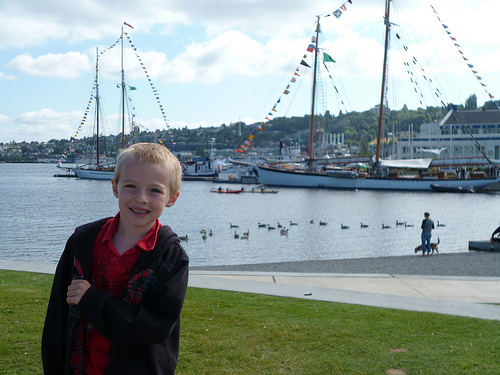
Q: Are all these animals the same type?
A: No, there are both dogs and birds.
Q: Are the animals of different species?
A: Yes, they are dogs and birds.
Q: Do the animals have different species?
A: Yes, they are dogs and birds.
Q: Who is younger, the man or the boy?
A: The boy is younger than the man.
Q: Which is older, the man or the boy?
A: The man is older than the boy.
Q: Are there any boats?
A: Yes, there is a boat.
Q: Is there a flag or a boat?
A: Yes, there is a boat.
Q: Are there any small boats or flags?
A: Yes, there is a small boat.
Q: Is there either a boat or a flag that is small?
A: Yes, the boat is small.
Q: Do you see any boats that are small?
A: Yes, there is a small boat.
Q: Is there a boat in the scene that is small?
A: Yes, there is a boat that is small.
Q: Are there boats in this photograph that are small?
A: Yes, there is a boat that is small.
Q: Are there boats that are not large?
A: Yes, there is a small boat.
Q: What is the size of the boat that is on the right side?
A: The boat is small.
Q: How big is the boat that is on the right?
A: The boat is small.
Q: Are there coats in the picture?
A: Yes, there is a coat.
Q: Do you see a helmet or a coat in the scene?
A: Yes, there is a coat.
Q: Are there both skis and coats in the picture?
A: No, there is a coat but no skis.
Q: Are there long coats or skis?
A: Yes, there is a long coat.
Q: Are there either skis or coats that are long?
A: Yes, the coat is long.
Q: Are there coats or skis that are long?
A: Yes, the coat is long.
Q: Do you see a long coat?
A: Yes, there is a long coat.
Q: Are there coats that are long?
A: Yes, there is a coat that is long.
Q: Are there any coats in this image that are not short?
A: Yes, there is a long coat.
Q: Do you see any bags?
A: No, there are no bags.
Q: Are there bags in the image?
A: No, there are no bags.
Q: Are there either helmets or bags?
A: No, there are no bags or helmets.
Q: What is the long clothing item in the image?
A: The clothing item is a coat.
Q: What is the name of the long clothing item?
A: The clothing item is a coat.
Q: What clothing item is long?
A: The clothing item is a coat.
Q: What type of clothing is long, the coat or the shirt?
A: The coat is long.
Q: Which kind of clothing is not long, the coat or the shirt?
A: The shirt is not long.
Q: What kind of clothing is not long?
A: The clothing is a shirt.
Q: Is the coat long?
A: Yes, the coat is long.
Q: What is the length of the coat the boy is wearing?
A: The coat is long.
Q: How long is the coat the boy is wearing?
A: The coat is long.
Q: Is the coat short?
A: No, the coat is long.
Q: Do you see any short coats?
A: No, there is a coat but it is long.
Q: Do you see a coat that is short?
A: No, there is a coat but it is long.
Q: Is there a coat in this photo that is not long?
A: No, there is a coat but it is long.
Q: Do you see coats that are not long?
A: No, there is a coat but it is long.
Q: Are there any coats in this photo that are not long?
A: No, there is a coat but it is long.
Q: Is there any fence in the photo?
A: No, there are no fences.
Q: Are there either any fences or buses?
A: No, there are no fences or buses.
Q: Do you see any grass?
A: Yes, there is grass.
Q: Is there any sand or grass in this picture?
A: Yes, there is grass.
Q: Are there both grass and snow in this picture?
A: No, there is grass but no snow.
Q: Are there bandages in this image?
A: No, there are no bandages.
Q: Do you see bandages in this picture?
A: No, there are no bandages.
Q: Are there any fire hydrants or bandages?
A: No, there are no bandages or fire hydrants.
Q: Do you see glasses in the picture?
A: No, there are no glasses.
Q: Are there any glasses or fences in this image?
A: No, there are no glasses or fences.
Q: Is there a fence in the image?
A: No, there are no fences.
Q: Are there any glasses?
A: No, there are no glasses.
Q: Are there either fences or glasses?
A: No, there are no glasses or fences.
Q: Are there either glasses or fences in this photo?
A: No, there are no glasses or fences.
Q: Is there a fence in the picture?
A: No, there are no fences.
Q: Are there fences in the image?
A: No, there are no fences.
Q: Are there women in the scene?
A: No, there are no women.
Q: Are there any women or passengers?
A: No, there are no women or passengers.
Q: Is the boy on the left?
A: Yes, the boy is on the left of the image.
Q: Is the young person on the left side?
A: Yes, the boy is on the left of the image.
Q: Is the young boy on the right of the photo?
A: No, the boy is on the left of the image.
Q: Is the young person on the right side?
A: No, the boy is on the left of the image.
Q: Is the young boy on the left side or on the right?
A: The boy is on the left of the image.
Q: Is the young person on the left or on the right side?
A: The boy is on the left of the image.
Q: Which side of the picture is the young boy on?
A: The boy is on the left of the image.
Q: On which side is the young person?
A: The boy is on the left of the image.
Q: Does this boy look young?
A: Yes, the boy is young.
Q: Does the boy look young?
A: Yes, the boy is young.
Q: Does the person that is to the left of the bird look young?
A: Yes, the boy is young.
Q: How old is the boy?
A: The boy is young.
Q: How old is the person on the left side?
A: The boy is young.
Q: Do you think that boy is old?
A: No, the boy is young.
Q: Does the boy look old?
A: No, the boy is young.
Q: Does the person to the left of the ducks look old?
A: No, the boy is young.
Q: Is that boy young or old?
A: The boy is young.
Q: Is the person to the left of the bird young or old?
A: The boy is young.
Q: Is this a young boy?
A: Yes, this is a young boy.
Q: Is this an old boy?
A: No, this is a young boy.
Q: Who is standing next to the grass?
A: The boy is standing next to the grass.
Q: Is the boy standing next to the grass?
A: Yes, the boy is standing next to the grass.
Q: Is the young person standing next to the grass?
A: Yes, the boy is standing next to the grass.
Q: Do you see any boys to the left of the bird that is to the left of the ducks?
A: Yes, there is a boy to the left of the bird.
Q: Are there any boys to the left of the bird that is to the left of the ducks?
A: Yes, there is a boy to the left of the bird.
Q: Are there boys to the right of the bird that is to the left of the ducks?
A: No, the boy is to the left of the bird.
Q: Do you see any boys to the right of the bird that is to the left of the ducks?
A: No, the boy is to the left of the bird.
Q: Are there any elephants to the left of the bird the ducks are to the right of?
A: No, there is a boy to the left of the bird.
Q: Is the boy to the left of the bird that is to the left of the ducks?
A: Yes, the boy is to the left of the bird.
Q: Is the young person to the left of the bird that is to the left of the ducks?
A: Yes, the boy is to the left of the bird.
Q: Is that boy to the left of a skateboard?
A: No, the boy is to the left of the bird.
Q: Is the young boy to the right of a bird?
A: No, the boy is to the left of a bird.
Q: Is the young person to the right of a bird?
A: No, the boy is to the left of a bird.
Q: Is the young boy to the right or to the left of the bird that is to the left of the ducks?
A: The boy is to the left of the bird.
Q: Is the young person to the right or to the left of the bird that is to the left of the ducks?
A: The boy is to the left of the bird.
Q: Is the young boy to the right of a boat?
A: No, the boy is to the left of a boat.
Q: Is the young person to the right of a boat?
A: No, the boy is to the left of a boat.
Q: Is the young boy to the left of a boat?
A: Yes, the boy is to the left of a boat.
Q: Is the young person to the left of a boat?
A: Yes, the boy is to the left of a boat.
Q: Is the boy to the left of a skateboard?
A: No, the boy is to the left of a boat.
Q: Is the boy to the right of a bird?
A: No, the boy is to the left of a bird.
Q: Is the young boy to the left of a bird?
A: Yes, the boy is to the left of a bird.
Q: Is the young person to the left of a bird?
A: Yes, the boy is to the left of a bird.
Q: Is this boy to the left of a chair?
A: No, the boy is to the left of a bird.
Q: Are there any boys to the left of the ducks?
A: Yes, there is a boy to the left of the ducks.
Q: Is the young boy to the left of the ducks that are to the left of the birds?
A: Yes, the boy is to the left of the ducks.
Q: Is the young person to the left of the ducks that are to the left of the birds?
A: Yes, the boy is to the left of the ducks.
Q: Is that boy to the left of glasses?
A: No, the boy is to the left of the ducks.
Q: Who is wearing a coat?
A: The boy is wearing a coat.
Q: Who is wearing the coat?
A: The boy is wearing a coat.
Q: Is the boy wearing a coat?
A: Yes, the boy is wearing a coat.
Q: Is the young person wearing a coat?
A: Yes, the boy is wearing a coat.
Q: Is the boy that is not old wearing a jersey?
A: No, the boy is wearing a coat.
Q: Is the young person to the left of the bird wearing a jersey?
A: No, the boy is wearing a coat.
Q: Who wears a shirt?
A: The boy wears a shirt.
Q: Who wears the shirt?
A: The boy wears a shirt.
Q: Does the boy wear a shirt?
A: Yes, the boy wears a shirt.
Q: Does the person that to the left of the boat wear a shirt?
A: Yes, the boy wears a shirt.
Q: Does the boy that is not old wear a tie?
A: No, the boy wears a shirt.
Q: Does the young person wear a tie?
A: No, the boy wears a shirt.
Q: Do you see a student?
A: No, there are no students.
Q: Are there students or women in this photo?
A: No, there are no students or women.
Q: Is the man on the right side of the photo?
A: Yes, the man is on the right of the image.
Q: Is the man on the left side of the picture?
A: No, the man is on the right of the image.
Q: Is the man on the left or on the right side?
A: The man is on the right of the image.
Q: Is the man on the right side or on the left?
A: The man is on the right of the image.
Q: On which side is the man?
A: The man is on the right of the image.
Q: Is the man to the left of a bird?
A: No, the man is to the right of a bird.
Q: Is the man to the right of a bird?
A: Yes, the man is to the right of a bird.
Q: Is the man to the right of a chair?
A: No, the man is to the right of a bird.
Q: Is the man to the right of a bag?
A: No, the man is to the right of a bird.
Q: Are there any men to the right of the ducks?
A: Yes, there is a man to the right of the ducks.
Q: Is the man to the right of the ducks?
A: Yes, the man is to the right of the ducks.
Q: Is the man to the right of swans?
A: No, the man is to the right of the ducks.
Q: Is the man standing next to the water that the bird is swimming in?
A: Yes, the man is standing next to the water.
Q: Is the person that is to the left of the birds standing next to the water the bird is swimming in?
A: Yes, the man is standing next to the water.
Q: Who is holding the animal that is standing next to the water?
A: The man is holding the dog.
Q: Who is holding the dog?
A: The man is holding the dog.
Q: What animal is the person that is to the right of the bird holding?
A: The man is holding the dog.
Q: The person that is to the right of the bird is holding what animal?
A: The man is holding the dog.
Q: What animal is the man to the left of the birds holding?
A: The man is holding the dog.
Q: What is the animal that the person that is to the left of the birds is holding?
A: The animal is a dog.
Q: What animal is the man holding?
A: The man is holding the dog.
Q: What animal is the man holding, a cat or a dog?
A: The man is holding a dog.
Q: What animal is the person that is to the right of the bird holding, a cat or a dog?
A: The man is holding a dog.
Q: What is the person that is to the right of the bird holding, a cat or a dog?
A: The man is holding a dog.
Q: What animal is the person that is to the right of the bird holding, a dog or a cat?
A: The man is holding a dog.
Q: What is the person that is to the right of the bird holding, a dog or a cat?
A: The man is holding a dog.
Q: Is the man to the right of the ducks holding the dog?
A: Yes, the man is holding the dog.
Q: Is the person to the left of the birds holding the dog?
A: Yes, the man is holding the dog.